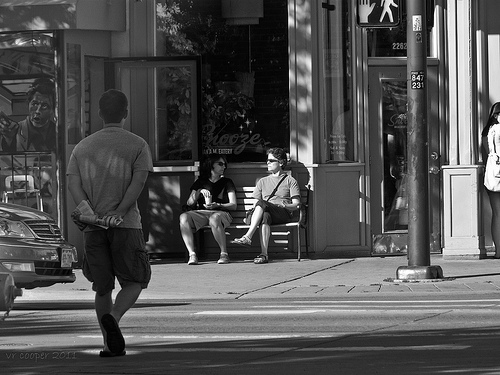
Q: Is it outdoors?
A: Yes, it is outdoors.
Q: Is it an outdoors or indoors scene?
A: It is outdoors.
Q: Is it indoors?
A: No, it is outdoors.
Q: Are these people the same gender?
A: No, they are both male and female.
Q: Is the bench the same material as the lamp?
A: No, the bench is made of wood and the lamp is made of metal.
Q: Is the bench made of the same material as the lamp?
A: No, the bench is made of wood and the lamp is made of metal.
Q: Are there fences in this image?
A: No, there are no fences.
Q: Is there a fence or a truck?
A: No, there are no fences or trucks.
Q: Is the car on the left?
A: Yes, the car is on the left of the image.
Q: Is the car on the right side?
A: No, the car is on the left of the image.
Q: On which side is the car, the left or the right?
A: The car is on the left of the image.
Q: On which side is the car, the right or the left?
A: The car is on the left of the image.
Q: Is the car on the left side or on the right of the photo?
A: The car is on the left of the image.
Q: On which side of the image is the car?
A: The car is on the left of the image.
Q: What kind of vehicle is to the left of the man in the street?
A: The vehicle is a car.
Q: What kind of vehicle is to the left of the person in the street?
A: The vehicle is a car.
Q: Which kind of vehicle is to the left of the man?
A: The vehicle is a car.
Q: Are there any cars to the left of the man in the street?
A: Yes, there is a car to the left of the man.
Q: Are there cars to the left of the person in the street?
A: Yes, there is a car to the left of the man.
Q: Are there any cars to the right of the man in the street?
A: No, the car is to the left of the man.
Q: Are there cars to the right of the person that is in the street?
A: No, the car is to the left of the man.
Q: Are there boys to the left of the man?
A: No, there is a car to the left of the man.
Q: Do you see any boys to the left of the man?
A: No, there is a car to the left of the man.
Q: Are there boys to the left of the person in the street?
A: No, there is a car to the left of the man.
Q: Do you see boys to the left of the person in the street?
A: No, there is a car to the left of the man.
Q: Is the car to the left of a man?
A: Yes, the car is to the left of a man.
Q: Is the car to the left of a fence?
A: No, the car is to the left of a man.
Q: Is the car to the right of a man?
A: No, the car is to the left of a man.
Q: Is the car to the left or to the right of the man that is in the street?
A: The car is to the left of the man.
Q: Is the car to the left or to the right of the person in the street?
A: The car is to the left of the man.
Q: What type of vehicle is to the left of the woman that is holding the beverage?
A: The vehicle is a car.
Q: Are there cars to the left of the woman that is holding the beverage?
A: Yes, there is a car to the left of the woman.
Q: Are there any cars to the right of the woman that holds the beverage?
A: No, the car is to the left of the woman.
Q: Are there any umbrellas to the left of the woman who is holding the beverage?
A: No, there is a car to the left of the woman.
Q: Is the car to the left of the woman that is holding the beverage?
A: Yes, the car is to the left of the woman.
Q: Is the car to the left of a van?
A: No, the car is to the left of the woman.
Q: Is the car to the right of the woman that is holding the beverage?
A: No, the car is to the left of the woman.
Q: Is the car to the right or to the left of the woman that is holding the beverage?
A: The car is to the left of the woman.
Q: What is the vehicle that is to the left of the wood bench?
A: The vehicle is a car.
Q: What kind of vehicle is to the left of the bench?
A: The vehicle is a car.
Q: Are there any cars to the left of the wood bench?
A: Yes, there is a car to the left of the bench.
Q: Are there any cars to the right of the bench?
A: No, the car is to the left of the bench.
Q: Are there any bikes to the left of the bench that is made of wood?
A: No, there is a car to the left of the bench.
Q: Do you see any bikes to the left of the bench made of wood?
A: No, there is a car to the left of the bench.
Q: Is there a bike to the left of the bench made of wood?
A: No, there is a car to the left of the bench.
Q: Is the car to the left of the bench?
A: Yes, the car is to the left of the bench.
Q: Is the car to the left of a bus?
A: No, the car is to the left of the bench.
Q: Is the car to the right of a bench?
A: No, the car is to the left of a bench.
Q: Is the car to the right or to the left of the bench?
A: The car is to the left of the bench.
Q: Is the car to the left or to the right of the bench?
A: The car is to the left of the bench.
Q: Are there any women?
A: Yes, there is a woman.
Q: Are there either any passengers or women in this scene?
A: Yes, there is a woman.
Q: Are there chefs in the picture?
A: No, there are no chefs.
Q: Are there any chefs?
A: No, there are no chefs.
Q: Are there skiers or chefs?
A: No, there are no chefs or skiers.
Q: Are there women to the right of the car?
A: Yes, there is a woman to the right of the car.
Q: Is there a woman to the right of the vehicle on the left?
A: Yes, there is a woman to the right of the car.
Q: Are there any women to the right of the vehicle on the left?
A: Yes, there is a woman to the right of the car.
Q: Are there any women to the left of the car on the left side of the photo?
A: No, the woman is to the right of the car.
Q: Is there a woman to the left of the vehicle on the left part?
A: No, the woman is to the right of the car.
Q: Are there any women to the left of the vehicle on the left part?
A: No, the woman is to the right of the car.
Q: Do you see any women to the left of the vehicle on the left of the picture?
A: No, the woman is to the right of the car.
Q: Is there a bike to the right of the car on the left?
A: No, there is a woman to the right of the car.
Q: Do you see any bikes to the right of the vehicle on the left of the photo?
A: No, there is a woman to the right of the car.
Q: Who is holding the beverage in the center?
A: The woman is holding the beverage.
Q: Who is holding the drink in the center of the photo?
A: The woman is holding the beverage.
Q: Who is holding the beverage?
A: The woman is holding the beverage.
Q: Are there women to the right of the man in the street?
A: Yes, there is a woman to the right of the man.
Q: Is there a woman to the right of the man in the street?
A: Yes, there is a woman to the right of the man.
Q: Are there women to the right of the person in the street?
A: Yes, there is a woman to the right of the man.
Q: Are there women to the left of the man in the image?
A: No, the woman is to the right of the man.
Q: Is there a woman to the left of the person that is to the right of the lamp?
A: No, the woman is to the right of the man.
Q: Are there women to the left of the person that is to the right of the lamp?
A: No, the woman is to the right of the man.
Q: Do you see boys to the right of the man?
A: No, there is a woman to the right of the man.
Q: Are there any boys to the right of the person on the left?
A: No, there is a woman to the right of the man.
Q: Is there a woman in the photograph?
A: Yes, there is a woman.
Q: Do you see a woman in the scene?
A: Yes, there is a woman.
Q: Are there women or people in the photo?
A: Yes, there is a woman.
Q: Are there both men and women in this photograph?
A: Yes, there are both a woman and a man.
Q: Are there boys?
A: No, there are no boys.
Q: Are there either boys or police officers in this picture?
A: No, there are no boys or police officers.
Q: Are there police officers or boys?
A: No, there are no boys or police officers.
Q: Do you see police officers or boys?
A: No, there are no boys or police officers.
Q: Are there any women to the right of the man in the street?
A: Yes, there is a woman to the right of the man.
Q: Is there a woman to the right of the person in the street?
A: Yes, there is a woman to the right of the man.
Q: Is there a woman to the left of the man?
A: No, the woman is to the right of the man.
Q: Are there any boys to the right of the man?
A: No, there is a woman to the right of the man.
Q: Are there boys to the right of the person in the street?
A: No, there is a woman to the right of the man.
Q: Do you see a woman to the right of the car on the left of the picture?
A: Yes, there is a woman to the right of the car.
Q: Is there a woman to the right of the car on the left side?
A: Yes, there is a woman to the right of the car.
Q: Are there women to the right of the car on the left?
A: Yes, there is a woman to the right of the car.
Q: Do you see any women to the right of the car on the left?
A: Yes, there is a woman to the right of the car.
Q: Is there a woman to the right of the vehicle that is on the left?
A: Yes, there is a woman to the right of the car.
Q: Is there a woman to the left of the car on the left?
A: No, the woman is to the right of the car.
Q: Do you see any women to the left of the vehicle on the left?
A: No, the woman is to the right of the car.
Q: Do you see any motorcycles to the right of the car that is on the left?
A: No, there is a woman to the right of the car.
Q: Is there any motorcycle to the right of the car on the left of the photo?
A: No, there is a woman to the right of the car.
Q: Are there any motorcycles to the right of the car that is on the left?
A: No, there is a woman to the right of the car.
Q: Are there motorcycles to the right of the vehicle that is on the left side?
A: No, there is a woman to the right of the car.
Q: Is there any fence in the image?
A: No, there are no fences.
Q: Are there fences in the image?
A: No, there are no fences.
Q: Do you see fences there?
A: No, there are no fences.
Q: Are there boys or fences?
A: No, there are no fences or boys.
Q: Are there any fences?
A: No, there are no fences.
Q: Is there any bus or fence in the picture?
A: No, there are no fences or buses.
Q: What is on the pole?
A: The sign is on the pole.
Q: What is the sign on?
A: The sign is on the pole.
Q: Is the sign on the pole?
A: Yes, the sign is on the pole.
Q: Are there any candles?
A: No, there are no candles.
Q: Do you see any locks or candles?
A: No, there are no candles or locks.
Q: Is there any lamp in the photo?
A: Yes, there is a lamp.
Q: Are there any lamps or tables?
A: Yes, there is a lamp.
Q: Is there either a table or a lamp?
A: Yes, there is a lamp.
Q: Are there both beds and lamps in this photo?
A: No, there is a lamp but no beds.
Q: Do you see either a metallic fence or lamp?
A: Yes, there is a metal lamp.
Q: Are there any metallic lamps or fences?
A: Yes, there is a metal lamp.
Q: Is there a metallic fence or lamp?
A: Yes, there is a metal lamp.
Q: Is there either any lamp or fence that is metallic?
A: Yes, the lamp is metallic.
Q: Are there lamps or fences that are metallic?
A: Yes, the lamp is metallic.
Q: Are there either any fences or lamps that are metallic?
A: Yes, the lamp is metallic.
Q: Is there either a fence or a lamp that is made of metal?
A: Yes, the lamp is made of metal.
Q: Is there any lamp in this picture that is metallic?
A: Yes, there is a metal lamp.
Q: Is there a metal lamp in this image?
A: Yes, there is a metal lamp.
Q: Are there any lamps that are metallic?
A: Yes, there is a lamp that is metallic.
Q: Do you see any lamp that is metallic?
A: Yes, there is a lamp that is metallic.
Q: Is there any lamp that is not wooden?
A: Yes, there is a metallic lamp.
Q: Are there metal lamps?
A: Yes, there is a lamp that is made of metal.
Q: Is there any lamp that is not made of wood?
A: Yes, there is a lamp that is made of metal.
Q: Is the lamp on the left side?
A: Yes, the lamp is on the left of the image.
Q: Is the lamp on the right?
A: No, the lamp is on the left of the image.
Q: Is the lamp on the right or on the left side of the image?
A: The lamp is on the left of the image.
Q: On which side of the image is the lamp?
A: The lamp is on the left of the image.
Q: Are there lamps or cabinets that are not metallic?
A: No, there is a lamp but it is metallic.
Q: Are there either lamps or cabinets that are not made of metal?
A: No, there is a lamp but it is made of metal.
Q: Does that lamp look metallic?
A: Yes, the lamp is metallic.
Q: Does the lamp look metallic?
A: Yes, the lamp is metallic.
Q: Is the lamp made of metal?
A: Yes, the lamp is made of metal.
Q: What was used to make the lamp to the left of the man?
A: The lamp is made of metal.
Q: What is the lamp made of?
A: The lamp is made of metal.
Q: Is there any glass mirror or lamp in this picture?
A: No, there is a lamp but it is metallic.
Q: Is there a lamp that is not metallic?
A: No, there is a lamp but it is metallic.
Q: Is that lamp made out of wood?
A: No, the lamp is made of metal.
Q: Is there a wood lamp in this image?
A: No, there is a lamp but it is made of metal.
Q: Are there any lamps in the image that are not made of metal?
A: No, there is a lamp but it is made of metal.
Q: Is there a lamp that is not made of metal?
A: No, there is a lamp but it is made of metal.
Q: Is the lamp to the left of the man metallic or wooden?
A: The lamp is metallic.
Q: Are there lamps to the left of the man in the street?
A: Yes, there is a lamp to the left of the man.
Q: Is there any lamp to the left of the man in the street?
A: Yes, there is a lamp to the left of the man.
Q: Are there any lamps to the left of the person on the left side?
A: Yes, there is a lamp to the left of the man.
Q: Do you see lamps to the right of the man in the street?
A: No, the lamp is to the left of the man.